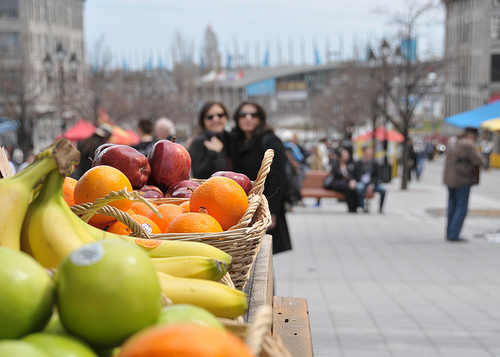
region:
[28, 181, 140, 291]
the apple is green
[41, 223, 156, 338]
the apple is green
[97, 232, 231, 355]
the apple is green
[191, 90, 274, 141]
Two dark haired women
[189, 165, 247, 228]
A round orange fruit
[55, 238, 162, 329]
A round green fruit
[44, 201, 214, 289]
A long yellow fruit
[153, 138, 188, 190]
A ripe red apple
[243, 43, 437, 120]
The sochi olympic stadium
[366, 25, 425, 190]
A dying tree out of focus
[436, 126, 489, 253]
A man in blue pants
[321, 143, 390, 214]
A couple sitting on a bench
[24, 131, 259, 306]
Assorted colored fruit to eat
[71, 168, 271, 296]
plenty fruits are visible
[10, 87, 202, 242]
plenty fruits are visible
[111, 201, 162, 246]
plenty fruits are visible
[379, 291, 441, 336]
concrete on the sidewalk.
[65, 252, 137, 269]
sticker on the apple.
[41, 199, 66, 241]
bananas in the basket.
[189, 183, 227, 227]
oranges in the basket.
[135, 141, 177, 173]
apples in the basket.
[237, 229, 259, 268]
wicker basket on the stand.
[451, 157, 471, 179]
brown coat on man.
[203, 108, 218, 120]
glasses on woman's face.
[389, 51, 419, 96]
bare limbs on tree.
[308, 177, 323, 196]
bench on the sidewalk.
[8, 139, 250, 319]
a ripe yellow banana bunch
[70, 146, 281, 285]
a brown wicker basket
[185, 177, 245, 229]
an orange fruit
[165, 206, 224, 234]
a ripe orange fruit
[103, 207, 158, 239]
a ripe orange fruit with sticker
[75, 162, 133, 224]
a ripe orange fruit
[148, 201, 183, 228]
a ripe orange fruit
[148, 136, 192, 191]
a ripe red apple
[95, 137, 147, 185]
a ripe red apple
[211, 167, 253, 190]
a ripe red apple